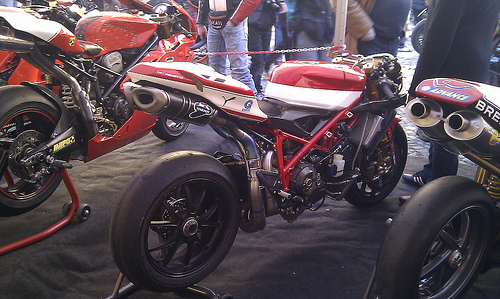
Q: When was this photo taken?
A: In the daytime.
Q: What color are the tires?
A: Black.